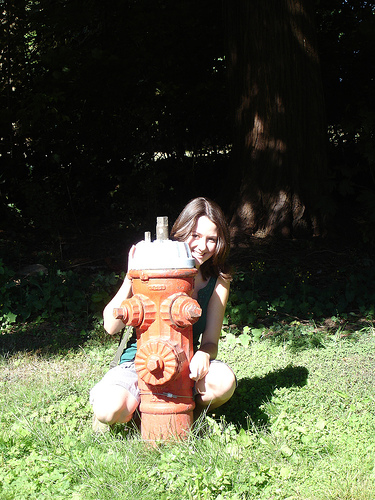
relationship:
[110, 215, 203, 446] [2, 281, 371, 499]
hydrant surrounded by grass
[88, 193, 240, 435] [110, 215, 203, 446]
girl kneeling behind hydrant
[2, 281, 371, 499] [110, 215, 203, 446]
grass around hydrant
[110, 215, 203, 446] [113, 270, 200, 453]
hydrant color red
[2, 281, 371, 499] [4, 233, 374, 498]
grass covering ground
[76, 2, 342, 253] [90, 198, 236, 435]
tree standing behind girl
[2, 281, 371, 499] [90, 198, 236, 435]
grass underneath girl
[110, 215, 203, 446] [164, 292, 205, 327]
hydrant has a spout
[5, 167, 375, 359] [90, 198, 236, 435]
shade behind girl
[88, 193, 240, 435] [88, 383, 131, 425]
girl has a knee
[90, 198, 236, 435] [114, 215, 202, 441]
girl holding onto an hydrant